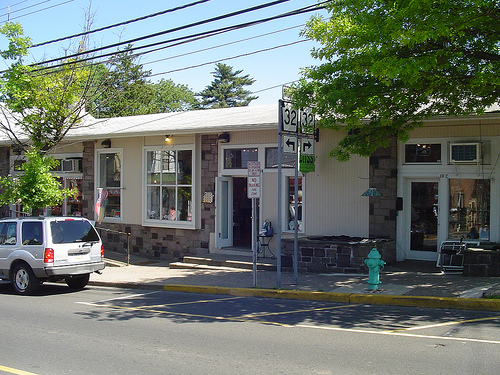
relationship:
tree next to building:
[333, 12, 493, 105] [12, 71, 497, 285]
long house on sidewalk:
[4, 104, 489, 261] [109, 255, 486, 299]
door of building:
[214, 175, 234, 248] [0, 103, 498, 265]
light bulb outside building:
[160, 135, 174, 147] [9, 105, 497, 287]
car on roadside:
[1, 206, 95, 293] [2, 273, 497, 373]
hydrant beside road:
[362, 246, 387, 288] [0, 282, 497, 374]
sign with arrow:
[298, 135, 313, 155] [300, 138, 312, 155]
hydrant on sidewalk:
[363, 248, 387, 290] [89, 262, 499, 314]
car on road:
[0, 216, 105, 296] [3, 260, 486, 373]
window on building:
[138, 143, 203, 230] [9, 105, 497, 287]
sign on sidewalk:
[300, 137, 314, 154] [82, 254, 495, 308]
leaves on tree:
[6, 145, 75, 211] [0, 48, 99, 211]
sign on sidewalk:
[245, 161, 263, 198] [80, 264, 498, 301]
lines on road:
[123, 279, 495, 326] [0, 260, 500, 375]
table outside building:
[253, 231, 278, 256] [58, 94, 373, 261]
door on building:
[214, 177, 234, 248] [0, 108, 374, 264]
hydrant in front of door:
[363, 248, 387, 290] [402, 174, 442, 261]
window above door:
[222, 146, 259, 170] [214, 175, 234, 248]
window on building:
[142, 144, 202, 231] [49, 101, 497, 294]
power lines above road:
[0, 0, 347, 159] [3, 260, 486, 373]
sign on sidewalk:
[300, 137, 314, 154] [91, 251, 499, 304]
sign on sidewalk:
[245, 161, 263, 198] [91, 251, 499, 304]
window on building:
[142, 144, 202, 231] [9, 105, 497, 287]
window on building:
[96, 149, 117, 220] [44, 98, 498, 276]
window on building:
[94, 148, 123, 222] [35, 93, 495, 286]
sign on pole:
[245, 161, 263, 198] [250, 198, 259, 285]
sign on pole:
[245, 161, 263, 198] [289, 102, 303, 298]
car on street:
[0, 216, 105, 296] [12, 298, 402, 371]